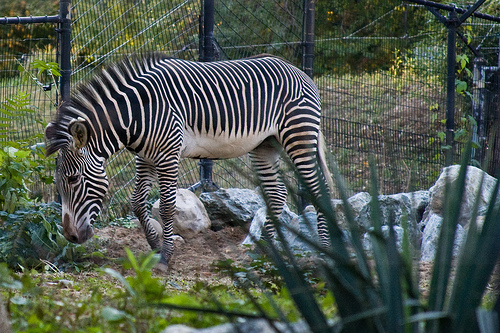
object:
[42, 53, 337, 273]
animal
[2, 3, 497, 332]
zoo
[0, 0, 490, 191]
fence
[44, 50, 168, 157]
hair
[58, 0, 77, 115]
bars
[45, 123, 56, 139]
ear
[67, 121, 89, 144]
ear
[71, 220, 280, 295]
dirt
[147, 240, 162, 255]
hoof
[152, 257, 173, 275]
hoof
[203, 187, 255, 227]
rock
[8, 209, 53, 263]
plant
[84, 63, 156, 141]
stripes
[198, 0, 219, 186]
post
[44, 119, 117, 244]
head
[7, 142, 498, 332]
ground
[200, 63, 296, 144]
stripes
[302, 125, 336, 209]
tail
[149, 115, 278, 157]
abdomen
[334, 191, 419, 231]
rocks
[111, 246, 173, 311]
plants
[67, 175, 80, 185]
eye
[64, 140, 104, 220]
side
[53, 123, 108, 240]
face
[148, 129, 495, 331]
plant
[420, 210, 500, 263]
rock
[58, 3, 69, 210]
fence post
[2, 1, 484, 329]
park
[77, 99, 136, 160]
neck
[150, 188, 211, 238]
boulder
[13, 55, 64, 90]
chain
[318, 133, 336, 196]
hair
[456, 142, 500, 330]
sisal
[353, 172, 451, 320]
right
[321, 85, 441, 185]
fencing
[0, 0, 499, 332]
day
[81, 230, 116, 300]
down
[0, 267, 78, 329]
plant